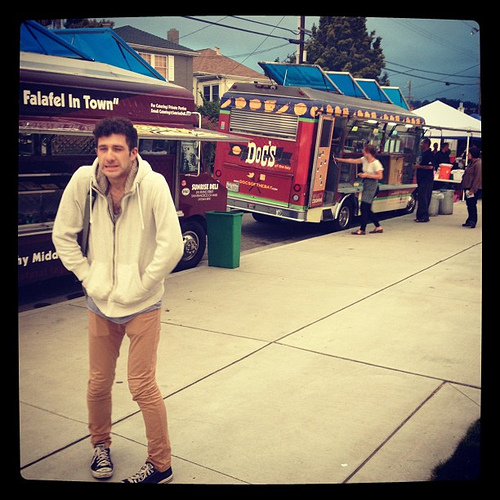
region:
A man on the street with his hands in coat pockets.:
[43, 112, 220, 484]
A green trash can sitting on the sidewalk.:
[200, 202, 272, 286]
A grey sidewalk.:
[241, 277, 411, 447]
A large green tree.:
[308, 19, 393, 76]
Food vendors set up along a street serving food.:
[212, 49, 480, 232]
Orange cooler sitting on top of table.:
[438, 162, 450, 182]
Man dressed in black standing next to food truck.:
[410, 132, 440, 231]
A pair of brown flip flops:
[349, 219, 399, 242]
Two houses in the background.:
[118, 20, 260, 95]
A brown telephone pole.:
[288, 16, 317, 61]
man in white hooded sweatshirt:
[44, 117, 199, 484]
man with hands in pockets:
[46, 114, 195, 486]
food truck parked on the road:
[206, 73, 428, 234]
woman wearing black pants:
[324, 143, 390, 243]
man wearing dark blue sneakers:
[49, 116, 196, 490]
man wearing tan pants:
[54, 121, 202, 485]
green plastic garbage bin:
[202, 205, 247, 272]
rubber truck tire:
[172, 217, 209, 272]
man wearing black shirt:
[401, 138, 443, 226]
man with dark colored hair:
[40, 113, 185, 485]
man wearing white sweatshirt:
[58, 107, 191, 499]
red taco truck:
[222, 74, 443, 220]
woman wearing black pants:
[332, 135, 405, 246]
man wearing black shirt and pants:
[411, 122, 441, 229]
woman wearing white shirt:
[330, 136, 413, 250]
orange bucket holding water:
[436, 161, 452, 186]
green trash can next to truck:
[200, 195, 247, 275]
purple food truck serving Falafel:
[19, 73, 231, 275]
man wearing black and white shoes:
[57, 110, 204, 482]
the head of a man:
[86, 111, 140, 185]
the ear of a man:
[126, 142, 141, 163]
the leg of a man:
[128, 315, 177, 460]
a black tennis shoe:
[119, 448, 176, 483]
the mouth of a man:
[94, 159, 126, 170]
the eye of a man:
[112, 142, 126, 157]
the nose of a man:
[103, 147, 118, 163]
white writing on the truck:
[239, 133, 279, 169]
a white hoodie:
[38, 147, 185, 317]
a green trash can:
[197, 202, 247, 272]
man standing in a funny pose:
[54, 114, 183, 485]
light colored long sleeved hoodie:
[51, 162, 184, 318]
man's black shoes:
[86, 442, 174, 486]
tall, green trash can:
[206, 210, 241, 267]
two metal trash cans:
[428, 188, 453, 215]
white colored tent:
[415, 98, 486, 138]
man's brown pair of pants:
[84, 304, 173, 471]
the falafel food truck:
[16, 67, 228, 269]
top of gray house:
[116, 24, 198, 101]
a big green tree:
[304, 20, 393, 88]